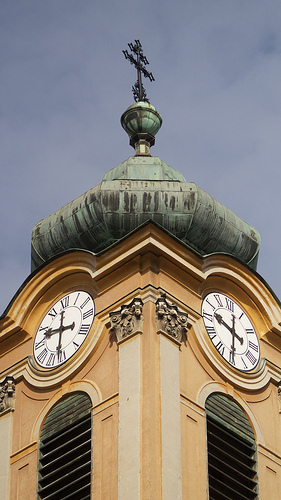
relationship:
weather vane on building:
[122, 37, 154, 101] [1, 101, 279, 498]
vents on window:
[41, 447, 99, 483] [29, 389, 110, 497]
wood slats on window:
[204, 397, 256, 438] [38, 388, 92, 496]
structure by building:
[29, 150, 264, 272] [7, 32, 280, 498]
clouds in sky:
[0, 0, 280, 316] [1, 4, 278, 272]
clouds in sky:
[0, 0, 280, 316] [0, 0, 279, 316]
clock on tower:
[198, 289, 265, 374] [9, 32, 263, 493]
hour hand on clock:
[43, 321, 74, 337] [200, 291, 260, 371]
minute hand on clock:
[229, 314, 235, 364] [200, 291, 260, 371]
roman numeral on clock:
[59, 294, 69, 309] [30, 288, 95, 368]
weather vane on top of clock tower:
[122, 34, 156, 101] [20, 281, 253, 449]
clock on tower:
[28, 290, 102, 378] [9, 32, 263, 493]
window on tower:
[29, 389, 110, 497] [122, 351, 265, 496]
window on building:
[29, 389, 94, 500] [0, 32, 281, 497]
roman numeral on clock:
[72, 293, 82, 305] [30, 288, 95, 368]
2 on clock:
[80, 297, 91, 306] [30, 288, 95, 368]